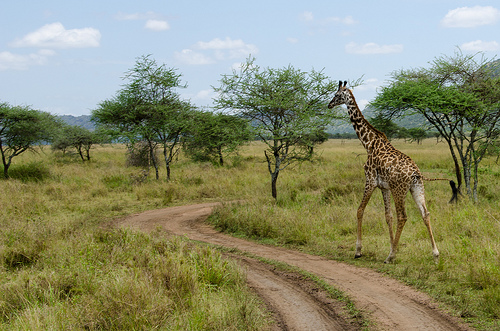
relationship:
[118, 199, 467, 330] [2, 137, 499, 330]
road in field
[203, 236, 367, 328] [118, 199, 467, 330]
median in road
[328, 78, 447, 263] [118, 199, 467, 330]
giraffe crossing road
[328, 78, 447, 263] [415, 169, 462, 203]
giraffe has tail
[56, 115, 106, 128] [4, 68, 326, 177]
mountains are behind trees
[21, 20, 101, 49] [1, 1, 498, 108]
cloud in sky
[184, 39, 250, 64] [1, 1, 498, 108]
cloud in sky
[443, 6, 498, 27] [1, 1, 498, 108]
cloud in sky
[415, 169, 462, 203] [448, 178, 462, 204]
tail has hair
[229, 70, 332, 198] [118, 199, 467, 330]
tree near road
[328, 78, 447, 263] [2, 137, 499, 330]
giraffe in field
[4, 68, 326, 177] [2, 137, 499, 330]
trees are in field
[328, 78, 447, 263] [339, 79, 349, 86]
giraffe has horns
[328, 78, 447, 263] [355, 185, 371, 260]
giraffe has leg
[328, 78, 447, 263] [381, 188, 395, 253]
giraffe has leg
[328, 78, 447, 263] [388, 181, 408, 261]
giraffe has leg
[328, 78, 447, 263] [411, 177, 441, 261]
giraffe has leg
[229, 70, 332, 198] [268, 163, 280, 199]
tree has trunk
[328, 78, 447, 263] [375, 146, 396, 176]
giraffe has spots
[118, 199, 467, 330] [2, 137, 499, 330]
road winds through field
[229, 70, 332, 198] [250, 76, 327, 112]
tree has leaves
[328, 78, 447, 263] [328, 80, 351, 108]
giraffe has head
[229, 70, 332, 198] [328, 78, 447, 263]
tree near giraffe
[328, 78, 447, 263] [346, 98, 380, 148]
giraffe has neck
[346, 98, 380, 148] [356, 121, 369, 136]
neck has spots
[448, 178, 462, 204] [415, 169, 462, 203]
hair on tail